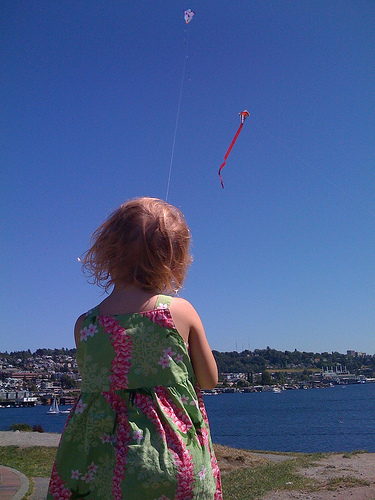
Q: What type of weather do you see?
A: It is clear.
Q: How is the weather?
A: It is clear.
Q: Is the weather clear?
A: Yes, it is clear.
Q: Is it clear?
A: Yes, it is clear.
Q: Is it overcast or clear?
A: It is clear.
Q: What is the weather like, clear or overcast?
A: It is clear.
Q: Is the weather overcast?
A: No, it is clear.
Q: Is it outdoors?
A: Yes, it is outdoors.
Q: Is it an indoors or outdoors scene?
A: It is outdoors.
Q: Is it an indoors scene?
A: No, it is outdoors.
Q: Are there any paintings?
A: No, there are no paintings.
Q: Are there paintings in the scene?
A: No, there are no paintings.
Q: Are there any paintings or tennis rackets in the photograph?
A: No, there are no paintings or tennis rackets.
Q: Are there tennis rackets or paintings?
A: No, there are no paintings or tennis rackets.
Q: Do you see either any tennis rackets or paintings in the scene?
A: No, there are no paintings or tennis rackets.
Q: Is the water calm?
A: Yes, the water is calm.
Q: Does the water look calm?
A: Yes, the water is calm.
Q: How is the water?
A: The water is calm.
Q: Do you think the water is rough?
A: No, the water is calm.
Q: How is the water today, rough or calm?
A: The water is calm.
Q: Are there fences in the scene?
A: No, there are no fences.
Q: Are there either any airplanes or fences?
A: No, there are no fences or airplanes.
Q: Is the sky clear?
A: Yes, the sky is clear.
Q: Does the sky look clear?
A: Yes, the sky is clear.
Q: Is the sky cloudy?
A: No, the sky is clear.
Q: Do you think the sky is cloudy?
A: No, the sky is clear.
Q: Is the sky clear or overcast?
A: The sky is clear.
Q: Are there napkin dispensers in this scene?
A: No, there are no napkin dispensers.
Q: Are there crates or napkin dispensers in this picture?
A: No, there are no napkin dispensers or crates.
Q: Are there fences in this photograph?
A: No, there are no fences.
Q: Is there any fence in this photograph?
A: No, there are no fences.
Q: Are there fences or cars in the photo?
A: No, there are no fences or cars.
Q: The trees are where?
A: The trees are on the mountain.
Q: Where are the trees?
A: The trees are on the mountain.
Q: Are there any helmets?
A: No, there are no helmets.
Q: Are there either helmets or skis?
A: No, there are no helmets or skis.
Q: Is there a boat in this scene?
A: Yes, there is a boat.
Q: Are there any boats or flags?
A: Yes, there is a boat.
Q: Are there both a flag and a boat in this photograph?
A: No, there is a boat but no flags.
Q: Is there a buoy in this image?
A: No, there are no buoys.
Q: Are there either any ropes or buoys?
A: No, there are no buoys or ropes.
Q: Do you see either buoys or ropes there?
A: No, there are no buoys or ropes.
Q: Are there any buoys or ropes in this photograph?
A: No, there are no buoys or ropes.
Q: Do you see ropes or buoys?
A: No, there are no buoys or ropes.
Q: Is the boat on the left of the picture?
A: Yes, the boat is on the left of the image.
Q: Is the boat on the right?
A: No, the boat is on the left of the image.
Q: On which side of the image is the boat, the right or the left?
A: The boat is on the left of the image.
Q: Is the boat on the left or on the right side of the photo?
A: The boat is on the left of the image.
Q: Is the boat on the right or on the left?
A: The boat is on the left of the image.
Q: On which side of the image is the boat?
A: The boat is on the left of the image.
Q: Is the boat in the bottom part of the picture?
A: Yes, the boat is in the bottom of the image.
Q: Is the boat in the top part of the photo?
A: No, the boat is in the bottom of the image.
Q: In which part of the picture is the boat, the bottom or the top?
A: The boat is in the bottom of the image.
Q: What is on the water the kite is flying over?
A: The boat is on the water.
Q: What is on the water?
A: The boat is on the water.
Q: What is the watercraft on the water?
A: The watercraft is a boat.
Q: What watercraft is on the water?
A: The watercraft is a boat.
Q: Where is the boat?
A: The boat is on the water.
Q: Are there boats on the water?
A: Yes, there is a boat on the water.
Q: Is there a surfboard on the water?
A: No, there is a boat on the water.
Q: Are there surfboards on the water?
A: No, there is a boat on the water.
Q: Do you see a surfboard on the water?
A: No, there is a boat on the water.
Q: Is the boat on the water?
A: Yes, the boat is on the water.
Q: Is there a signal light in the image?
A: No, there are no traffic lights.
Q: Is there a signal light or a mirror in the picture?
A: No, there are no traffic lights or mirrors.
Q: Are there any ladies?
A: No, there are no ladies.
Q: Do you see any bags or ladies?
A: No, there are no ladies or bags.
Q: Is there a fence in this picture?
A: No, there are no fences.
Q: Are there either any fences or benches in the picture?
A: No, there are no fences or benches.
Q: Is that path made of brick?
A: Yes, the path is made of brick.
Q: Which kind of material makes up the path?
A: The path is made of brick.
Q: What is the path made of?
A: The path is made of brick.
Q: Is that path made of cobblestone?
A: No, the path is made of brick.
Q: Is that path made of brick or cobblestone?
A: The path is made of brick.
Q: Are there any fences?
A: No, there are no fences.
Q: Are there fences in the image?
A: No, there are no fences.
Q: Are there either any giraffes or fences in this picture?
A: No, there are no fences or giraffes.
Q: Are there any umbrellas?
A: No, there are no umbrellas.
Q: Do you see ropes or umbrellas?
A: No, there are no umbrellas or ropes.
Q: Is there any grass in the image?
A: Yes, there is grass.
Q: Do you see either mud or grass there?
A: Yes, there is grass.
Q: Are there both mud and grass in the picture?
A: No, there is grass but no mud.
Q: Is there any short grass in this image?
A: Yes, there is short grass.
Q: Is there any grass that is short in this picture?
A: Yes, there is short grass.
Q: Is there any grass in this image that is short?
A: Yes, there is grass that is short.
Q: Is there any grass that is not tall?
A: Yes, there is short grass.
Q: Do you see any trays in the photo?
A: No, there are no trays.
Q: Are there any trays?
A: No, there are no trays.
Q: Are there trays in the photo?
A: No, there are no trays.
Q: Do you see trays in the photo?
A: No, there are no trays.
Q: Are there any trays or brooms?
A: No, there are no trays or brooms.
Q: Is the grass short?
A: Yes, the grass is short.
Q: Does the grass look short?
A: Yes, the grass is short.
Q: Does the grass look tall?
A: No, the grass is short.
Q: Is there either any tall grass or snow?
A: No, there is grass but it is short.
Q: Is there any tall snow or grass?
A: No, there is grass but it is short.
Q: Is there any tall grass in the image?
A: No, there is grass but it is short.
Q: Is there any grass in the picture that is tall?
A: No, there is grass but it is short.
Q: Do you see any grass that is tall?
A: No, there is grass but it is short.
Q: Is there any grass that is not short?
A: No, there is grass but it is short.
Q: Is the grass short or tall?
A: The grass is short.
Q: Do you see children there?
A: Yes, there is a child.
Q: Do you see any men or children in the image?
A: Yes, there is a child.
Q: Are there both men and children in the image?
A: No, there is a child but no men.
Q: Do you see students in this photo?
A: No, there are no students.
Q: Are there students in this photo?
A: No, there are no students.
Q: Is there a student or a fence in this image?
A: No, there are no students or fences.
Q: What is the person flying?
A: The kid is flying the kite.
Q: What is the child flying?
A: The kid is flying the kite.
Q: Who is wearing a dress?
A: The child is wearing a dress.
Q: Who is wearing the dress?
A: The child is wearing a dress.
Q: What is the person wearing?
A: The kid is wearing a dress.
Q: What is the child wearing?
A: The kid is wearing a dress.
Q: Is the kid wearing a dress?
A: Yes, the kid is wearing a dress.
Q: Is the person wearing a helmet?
A: No, the child is wearing a dress.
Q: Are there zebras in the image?
A: No, there are no zebras.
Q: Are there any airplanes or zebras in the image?
A: No, there are no zebras or airplanes.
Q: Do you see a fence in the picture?
A: No, there are no fences.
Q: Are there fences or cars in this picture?
A: No, there are no fences or cars.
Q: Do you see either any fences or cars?
A: No, there are no fences or cars.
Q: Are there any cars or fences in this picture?
A: No, there are no fences or cars.